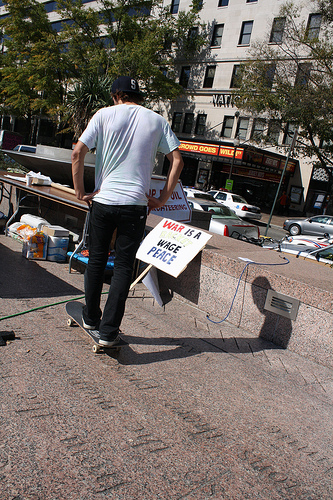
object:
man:
[70, 74, 183, 347]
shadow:
[104, 275, 292, 366]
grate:
[263, 289, 302, 322]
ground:
[0, 232, 333, 500]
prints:
[150, 445, 172, 453]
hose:
[205, 255, 290, 326]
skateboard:
[60, 294, 131, 359]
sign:
[135, 216, 215, 280]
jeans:
[77, 201, 148, 342]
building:
[139, 0, 333, 218]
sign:
[177, 141, 243, 159]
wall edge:
[222, 235, 332, 289]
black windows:
[203, 77, 216, 89]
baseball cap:
[108, 73, 150, 98]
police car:
[208, 188, 263, 223]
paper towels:
[47, 236, 58, 262]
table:
[0, 166, 89, 262]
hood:
[183, 188, 211, 196]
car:
[282, 209, 333, 236]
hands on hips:
[68, 145, 181, 205]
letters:
[162, 219, 175, 229]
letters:
[147, 246, 157, 254]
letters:
[173, 245, 181, 254]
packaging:
[21, 231, 48, 259]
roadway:
[238, 209, 294, 247]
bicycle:
[230, 231, 288, 250]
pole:
[129, 261, 152, 296]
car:
[187, 198, 261, 242]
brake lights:
[222, 225, 230, 237]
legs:
[67, 211, 89, 274]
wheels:
[90, 343, 100, 357]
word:
[163, 220, 185, 233]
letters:
[217, 94, 225, 104]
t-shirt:
[77, 100, 181, 208]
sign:
[148, 177, 193, 226]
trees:
[0, 0, 213, 145]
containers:
[46, 236, 70, 263]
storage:
[8, 212, 78, 253]